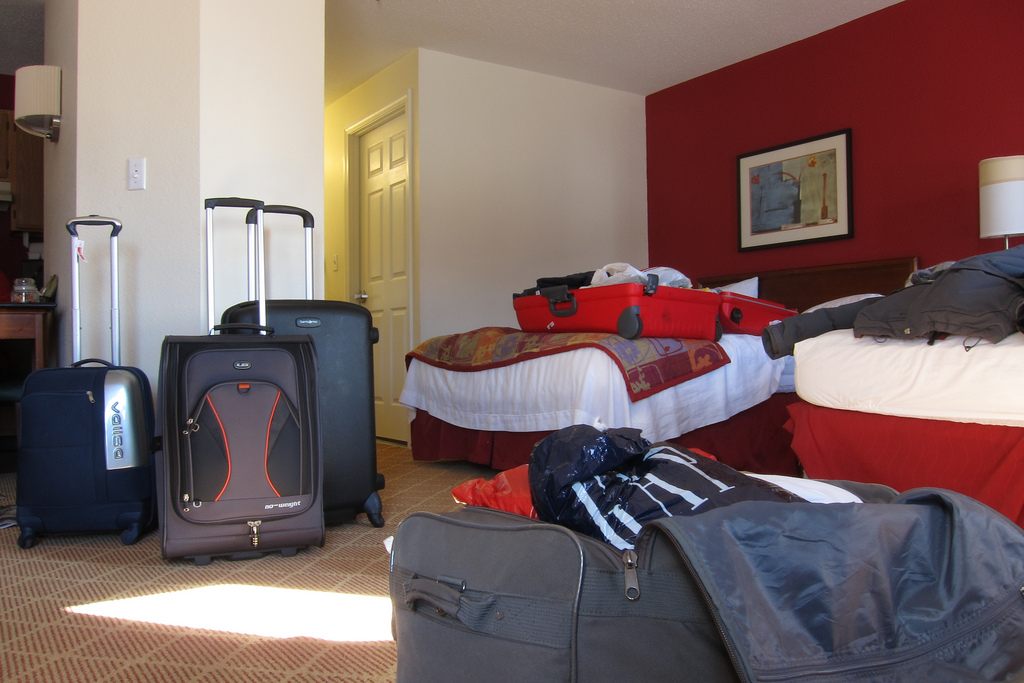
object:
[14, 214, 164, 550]
suitcase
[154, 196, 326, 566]
suitcase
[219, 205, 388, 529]
suitcase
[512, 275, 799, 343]
suitcase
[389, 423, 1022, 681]
bag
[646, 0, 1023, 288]
wall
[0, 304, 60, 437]
desk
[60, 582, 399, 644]
light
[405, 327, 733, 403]
blanket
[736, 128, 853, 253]
painting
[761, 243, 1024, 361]
jacket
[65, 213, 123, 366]
handle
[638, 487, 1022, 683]
flap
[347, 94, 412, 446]
door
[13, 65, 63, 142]
fixture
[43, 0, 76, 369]
wall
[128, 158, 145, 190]
switch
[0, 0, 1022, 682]
room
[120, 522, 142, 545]
wheel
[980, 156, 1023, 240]
shade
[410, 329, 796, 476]
bed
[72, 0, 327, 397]
wall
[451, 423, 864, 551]
clothes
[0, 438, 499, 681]
floor